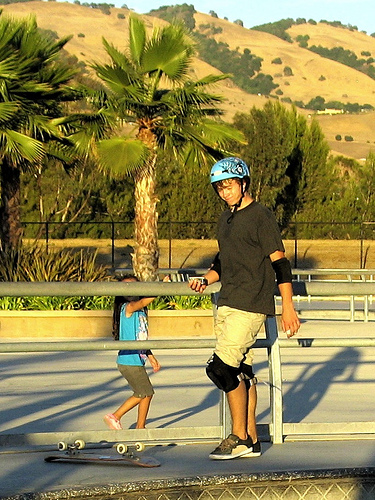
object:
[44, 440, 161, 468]
skateboard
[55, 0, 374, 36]
sky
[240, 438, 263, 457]
sneaker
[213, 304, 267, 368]
shorts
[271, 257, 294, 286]
pads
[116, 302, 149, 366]
shirt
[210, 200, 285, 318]
gray shirt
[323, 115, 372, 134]
ground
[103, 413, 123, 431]
sneaker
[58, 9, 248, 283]
palm tree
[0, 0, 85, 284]
palm tree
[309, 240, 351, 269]
brown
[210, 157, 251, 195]
helmet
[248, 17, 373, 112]
hills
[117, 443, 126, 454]
wheels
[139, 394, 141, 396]
button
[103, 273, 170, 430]
girl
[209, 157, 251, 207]
head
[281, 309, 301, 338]
hand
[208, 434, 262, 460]
shoes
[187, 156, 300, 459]
boy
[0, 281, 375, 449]
railing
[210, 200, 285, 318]
shirt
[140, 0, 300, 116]
hills